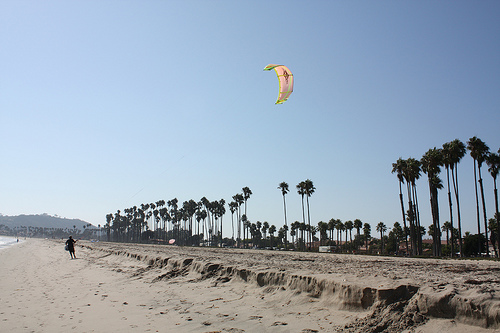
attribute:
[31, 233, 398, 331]
sand — some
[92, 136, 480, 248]
trees — palm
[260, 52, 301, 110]
yellow kite — in the sky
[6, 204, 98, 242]
bunch of mountains — in the distance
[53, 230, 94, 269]
person — in the distance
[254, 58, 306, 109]
kite in the sky — yellow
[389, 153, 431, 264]
trunks of palm trees — skinny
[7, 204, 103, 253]
mountain — in background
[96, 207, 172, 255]
trees on the edge — palm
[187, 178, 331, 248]
trees on the edge — palm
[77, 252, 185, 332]
area of the beach — sand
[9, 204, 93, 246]
terrain in the — in the distance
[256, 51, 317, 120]
fabric in the air — in the air